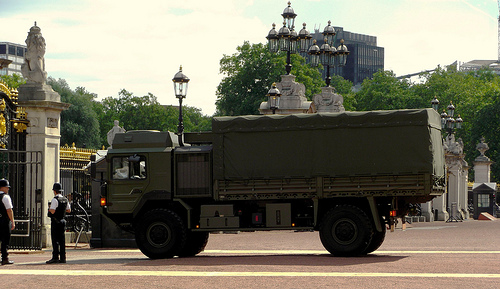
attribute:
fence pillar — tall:
[19, 20, 68, 250]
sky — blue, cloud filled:
[1, 0, 498, 117]